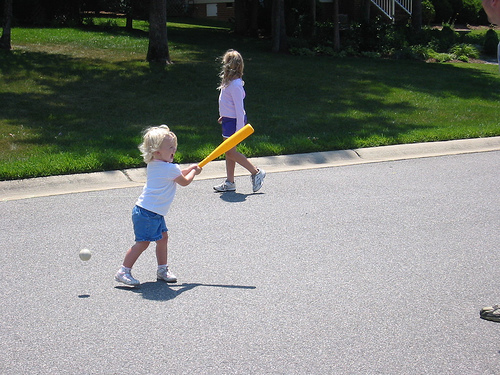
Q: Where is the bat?
A: In the nearest girl's hands.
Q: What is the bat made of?
A: Plastic.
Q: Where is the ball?
A: In the air.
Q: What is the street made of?
A: Asphalt.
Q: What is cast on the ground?
A: Shadows.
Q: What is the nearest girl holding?
A: A baseball bat.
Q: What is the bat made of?
A: Plastic.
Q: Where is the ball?
A: Behind the girl.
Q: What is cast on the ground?
A: Shadows.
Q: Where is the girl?
A: On the pavement.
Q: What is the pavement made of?
A: Asphalt.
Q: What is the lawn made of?
A: Grass.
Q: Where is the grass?
A: On the lawn.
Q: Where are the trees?
A: On the grass.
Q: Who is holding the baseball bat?
A: The nearest girl.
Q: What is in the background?
A: Tree trunks in the yard.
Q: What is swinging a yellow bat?
A: The toddler.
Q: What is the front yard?
A: Lush and green.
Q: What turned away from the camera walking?
A: The girl.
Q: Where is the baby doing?
A: Playing ball.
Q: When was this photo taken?
A: During the day.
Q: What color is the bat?
A: Yellow.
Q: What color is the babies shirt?
A: White.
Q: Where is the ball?
A: Left side.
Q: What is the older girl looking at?
A: The grass.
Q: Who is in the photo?
A: Two kids.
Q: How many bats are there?
A: One.